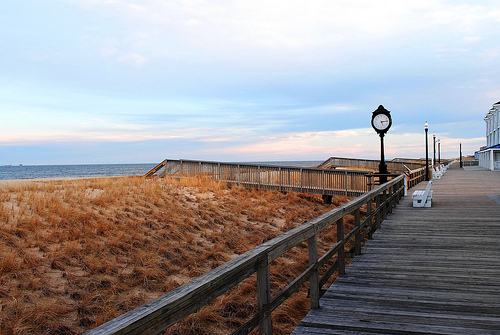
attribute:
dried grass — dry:
[90, 200, 190, 271]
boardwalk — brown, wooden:
[79, 159, 499, 334]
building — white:
[477, 97, 497, 196]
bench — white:
[430, 168, 448, 178]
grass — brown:
[115, 203, 242, 270]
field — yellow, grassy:
[6, 182, 320, 301]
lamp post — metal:
[402, 104, 442, 203]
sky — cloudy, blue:
[0, 0, 498, 170]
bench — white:
[410, 178, 433, 207]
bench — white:
[431, 167, 440, 177]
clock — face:
[363, 106, 398, 143]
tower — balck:
[369, 102, 400, 190]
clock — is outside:
[368, 102, 395, 137]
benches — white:
[410, 156, 466, 219]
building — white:
[460, 100, 497, 183]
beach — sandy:
[6, 156, 278, 268]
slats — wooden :
[392, 226, 469, 313]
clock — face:
[374, 113, 387, 132]